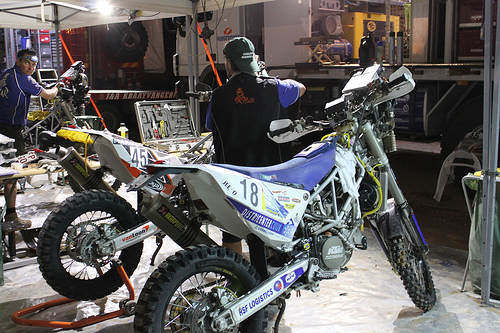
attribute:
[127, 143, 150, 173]
number — 45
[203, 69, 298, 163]
shirt — blue, black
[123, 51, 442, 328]
bike — black, blue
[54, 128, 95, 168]
rope — yellow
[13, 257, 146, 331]
bar — orange, metal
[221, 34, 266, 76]
hat — black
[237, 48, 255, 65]
letters — white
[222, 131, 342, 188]
seat — blue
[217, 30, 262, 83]
cap — black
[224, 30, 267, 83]
cap — black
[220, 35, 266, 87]
cap — black